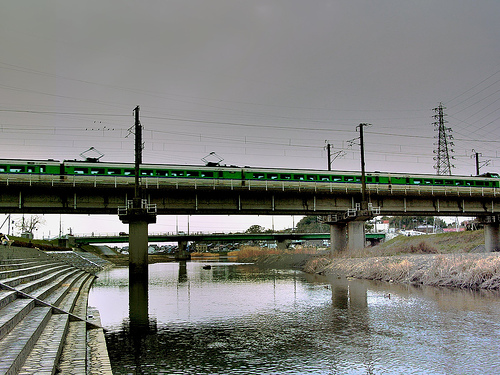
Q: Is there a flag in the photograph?
A: No, there are no flags.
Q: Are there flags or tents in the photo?
A: No, there are no flags or tents.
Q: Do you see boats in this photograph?
A: No, there are no boats.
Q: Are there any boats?
A: No, there are no boats.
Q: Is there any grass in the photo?
A: Yes, there is grass.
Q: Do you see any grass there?
A: Yes, there is grass.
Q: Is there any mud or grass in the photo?
A: Yes, there is grass.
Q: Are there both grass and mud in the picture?
A: No, there is grass but no mud.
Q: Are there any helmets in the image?
A: No, there are no helmets.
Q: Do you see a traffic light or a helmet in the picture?
A: No, there are no helmets or traffic lights.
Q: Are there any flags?
A: No, there are no flags.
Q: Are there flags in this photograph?
A: No, there are no flags.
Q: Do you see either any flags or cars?
A: No, there are no flags or cars.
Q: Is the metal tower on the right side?
A: Yes, the tower is on the right of the image.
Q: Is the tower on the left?
A: No, the tower is on the right of the image.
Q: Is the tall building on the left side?
A: No, the tower is on the right of the image.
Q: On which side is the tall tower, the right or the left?
A: The tower is on the right of the image.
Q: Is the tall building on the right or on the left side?
A: The tower is on the right of the image.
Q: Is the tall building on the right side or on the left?
A: The tower is on the right of the image.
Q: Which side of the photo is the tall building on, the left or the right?
A: The tower is on the right of the image.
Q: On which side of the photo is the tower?
A: The tower is on the right of the image.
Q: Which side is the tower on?
A: The tower is on the right of the image.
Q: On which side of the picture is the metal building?
A: The tower is on the right of the image.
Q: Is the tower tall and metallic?
A: Yes, the tower is tall and metallic.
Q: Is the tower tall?
A: Yes, the tower is tall.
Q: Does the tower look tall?
A: Yes, the tower is tall.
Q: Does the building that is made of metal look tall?
A: Yes, the tower is tall.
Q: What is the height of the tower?
A: The tower is tall.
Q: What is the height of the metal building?
A: The tower is tall.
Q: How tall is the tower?
A: The tower is tall.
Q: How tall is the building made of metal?
A: The tower is tall.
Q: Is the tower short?
A: No, the tower is tall.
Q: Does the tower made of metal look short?
A: No, the tower is tall.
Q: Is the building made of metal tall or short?
A: The tower is tall.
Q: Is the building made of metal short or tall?
A: The tower is tall.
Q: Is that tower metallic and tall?
A: Yes, the tower is metallic and tall.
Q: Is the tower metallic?
A: Yes, the tower is metallic.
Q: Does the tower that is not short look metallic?
A: Yes, the tower is metallic.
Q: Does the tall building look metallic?
A: Yes, the tower is metallic.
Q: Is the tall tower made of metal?
A: Yes, the tower is made of metal.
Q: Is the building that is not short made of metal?
A: Yes, the tower is made of metal.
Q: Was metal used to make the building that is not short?
A: Yes, the tower is made of metal.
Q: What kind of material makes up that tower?
A: The tower is made of metal.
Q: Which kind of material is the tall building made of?
A: The tower is made of metal.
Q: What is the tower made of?
A: The tower is made of metal.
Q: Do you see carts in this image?
A: No, there are no carts.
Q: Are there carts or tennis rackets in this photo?
A: No, there are no carts or tennis rackets.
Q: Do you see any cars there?
A: No, there are no cars.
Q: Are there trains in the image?
A: Yes, there is a train.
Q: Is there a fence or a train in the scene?
A: Yes, there is a train.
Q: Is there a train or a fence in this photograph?
A: Yes, there is a train.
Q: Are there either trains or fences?
A: Yes, there is a train.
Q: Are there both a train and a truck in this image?
A: No, there is a train but no trucks.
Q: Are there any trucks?
A: No, there are no trucks.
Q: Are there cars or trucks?
A: No, there are no trucks or cars.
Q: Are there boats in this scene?
A: No, there are no boats.